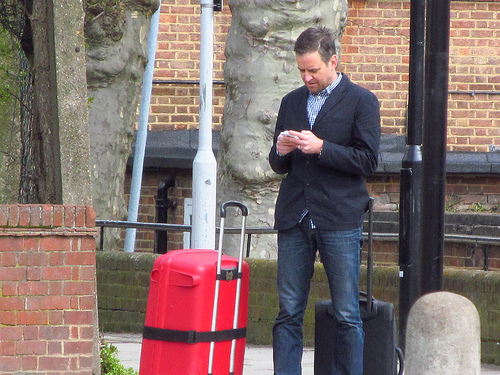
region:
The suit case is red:
[151, 260, 224, 368]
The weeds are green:
[96, 338, 122, 373]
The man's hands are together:
[264, 127, 365, 182]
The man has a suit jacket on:
[280, 76, 375, 243]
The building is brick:
[340, 25, 387, 70]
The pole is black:
[397, 53, 495, 290]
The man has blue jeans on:
[246, 202, 388, 364]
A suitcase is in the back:
[307, 250, 419, 370]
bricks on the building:
[0, 207, 96, 367]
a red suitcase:
[155, 231, 246, 371]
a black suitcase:
[336, 295, 391, 361]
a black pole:
[409, 38, 440, 283]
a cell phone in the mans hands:
[286, 127, 293, 137]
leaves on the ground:
[96, 335, 121, 370]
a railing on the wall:
[100, 217, 200, 258]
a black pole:
[147, 178, 172, 233]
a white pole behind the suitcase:
[195, 28, 218, 262]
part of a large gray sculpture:
[210, 0, 347, 258]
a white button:
[310, 113, 318, 120]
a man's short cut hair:
[293, 27, 336, 64]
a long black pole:
[392, 3, 441, 329]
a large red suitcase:
[140, 244, 249, 374]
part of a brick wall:
[0, 200, 102, 374]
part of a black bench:
[440, 210, 498, 252]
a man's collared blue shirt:
[305, 73, 346, 126]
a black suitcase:
[315, 294, 399, 374]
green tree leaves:
[101, 341, 134, 373]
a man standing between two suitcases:
[271, 25, 380, 372]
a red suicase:
[138, 199, 243, 373]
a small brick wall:
[4, 203, 100, 374]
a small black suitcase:
[313, 195, 403, 372]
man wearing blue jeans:
[274, 222, 364, 374]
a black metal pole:
[400, 1, 450, 373]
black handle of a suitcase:
[219, 200, 249, 213]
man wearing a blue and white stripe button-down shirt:
[300, 70, 343, 230]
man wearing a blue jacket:
[270, 70, 379, 230]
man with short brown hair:
[293, 26, 339, 93]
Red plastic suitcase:
[136, 200, 253, 373]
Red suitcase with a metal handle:
[135, 199, 252, 374]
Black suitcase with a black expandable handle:
[309, 193, 404, 373]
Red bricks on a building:
[1, 200, 98, 373]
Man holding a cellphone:
[266, 23, 381, 373]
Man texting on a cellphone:
[266, 23, 383, 373]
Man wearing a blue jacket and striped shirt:
[266, 25, 386, 374]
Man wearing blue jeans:
[265, 25, 382, 374]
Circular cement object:
[399, 285, 483, 372]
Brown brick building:
[117, 0, 499, 274]